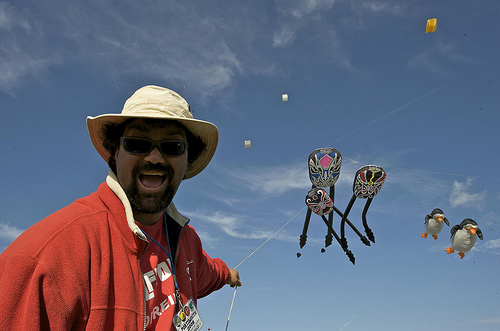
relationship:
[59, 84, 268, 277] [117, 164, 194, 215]
man has beard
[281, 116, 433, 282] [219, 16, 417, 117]
kites in sky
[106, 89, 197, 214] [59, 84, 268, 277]
head of man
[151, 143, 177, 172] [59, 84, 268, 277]
nose of man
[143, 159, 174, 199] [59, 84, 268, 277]
mouth of man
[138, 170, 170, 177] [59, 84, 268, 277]
teeth of man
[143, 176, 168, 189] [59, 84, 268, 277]
tongue of man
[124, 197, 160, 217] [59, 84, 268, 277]
chin of man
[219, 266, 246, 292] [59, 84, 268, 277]
hand of man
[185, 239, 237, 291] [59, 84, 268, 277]
arm of man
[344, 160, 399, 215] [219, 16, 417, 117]
kite in sky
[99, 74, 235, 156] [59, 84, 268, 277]
hat on man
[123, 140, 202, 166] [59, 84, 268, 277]
sunglasses on man